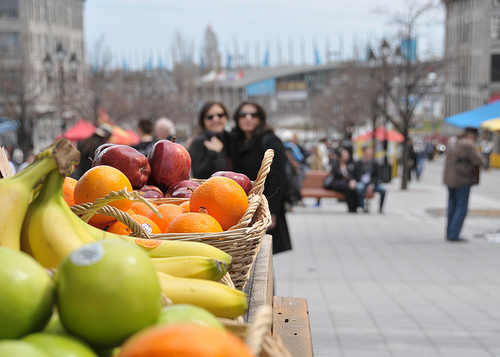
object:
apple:
[1, 247, 54, 339]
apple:
[54, 239, 161, 347]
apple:
[153, 303, 226, 330]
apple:
[20, 332, 100, 357]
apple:
[1, 338, 48, 357]